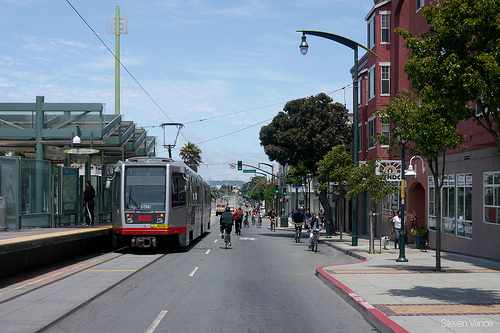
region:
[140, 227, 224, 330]
White lines on the road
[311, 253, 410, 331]
Red curb of a sidewalk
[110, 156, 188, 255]
The front of a train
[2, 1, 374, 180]
White clouds in the sky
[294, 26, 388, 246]
A tall street lamp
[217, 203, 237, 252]
Person riding a bicycle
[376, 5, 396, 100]
Two windows on a building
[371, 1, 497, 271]
Green leaves on two trees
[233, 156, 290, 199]
Traffic lights are lit up green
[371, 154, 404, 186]
White sign on a building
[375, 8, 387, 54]
Small window on a building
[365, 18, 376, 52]
Small window on a building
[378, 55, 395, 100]
Small window on a building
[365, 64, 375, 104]
Small window on a building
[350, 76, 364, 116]
Small window on a building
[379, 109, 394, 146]
Small window on a building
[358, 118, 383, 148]
Small window on a building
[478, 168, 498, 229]
Small window on a building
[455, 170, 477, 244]
Small window on a building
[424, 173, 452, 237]
Small window on a building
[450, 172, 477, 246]
Small window on a building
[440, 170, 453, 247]
Small window on a building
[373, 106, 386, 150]
Small window on a building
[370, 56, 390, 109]
Small window on a building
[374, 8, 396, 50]
Small window on a building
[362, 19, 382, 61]
Small window on a building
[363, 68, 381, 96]
Small window on a building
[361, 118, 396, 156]
Small window on a building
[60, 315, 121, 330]
part of the paved road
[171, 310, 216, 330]
part of the paved road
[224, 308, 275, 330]
part of the paved road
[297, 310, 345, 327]
part of the paved road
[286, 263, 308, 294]
part of the paved road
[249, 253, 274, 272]
part of the paved road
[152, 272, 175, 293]
part of the paved road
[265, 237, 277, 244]
part of the paved road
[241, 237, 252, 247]
part of the paved road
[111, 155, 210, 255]
a silver and red train car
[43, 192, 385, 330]
a paved city street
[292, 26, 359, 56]
an overhead street light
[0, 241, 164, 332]
a set of train tracks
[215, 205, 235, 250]
a man on bicycle in street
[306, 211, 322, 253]
a man on bicycle in street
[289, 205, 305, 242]
a man on bicycle in street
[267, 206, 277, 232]
a man on bicycle in street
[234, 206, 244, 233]
a man on bicycle in street